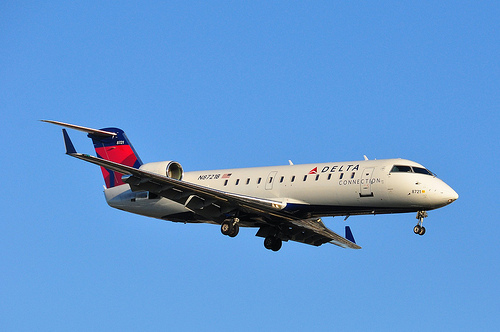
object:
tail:
[38, 114, 144, 189]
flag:
[221, 172, 232, 178]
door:
[360, 167, 374, 197]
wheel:
[220, 219, 232, 235]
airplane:
[36, 118, 459, 251]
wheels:
[227, 222, 239, 238]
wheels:
[265, 235, 282, 252]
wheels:
[413, 225, 426, 236]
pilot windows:
[389, 164, 433, 176]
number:
[196, 173, 220, 181]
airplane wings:
[60, 128, 312, 229]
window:
[389, 164, 435, 177]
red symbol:
[307, 166, 317, 175]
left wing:
[295, 216, 363, 250]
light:
[119, 174, 143, 187]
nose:
[390, 162, 460, 208]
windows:
[223, 172, 357, 187]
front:
[289, 154, 459, 237]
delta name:
[320, 162, 360, 172]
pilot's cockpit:
[388, 163, 436, 177]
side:
[105, 158, 443, 206]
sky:
[0, 0, 499, 331]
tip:
[343, 225, 357, 244]